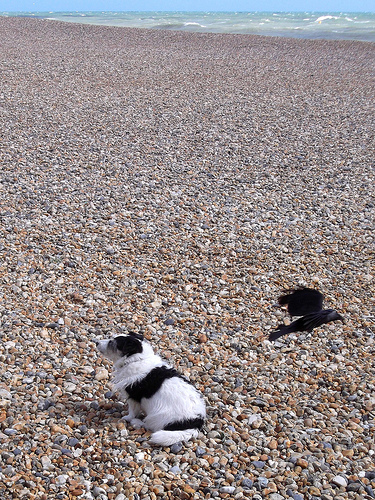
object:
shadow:
[66, 418, 74, 428]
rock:
[102, 402, 113, 410]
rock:
[39, 329, 48, 337]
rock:
[248, 414, 257, 426]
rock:
[94, 368, 107, 379]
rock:
[173, 221, 179, 227]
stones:
[136, 212, 144, 218]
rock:
[239, 477, 252, 489]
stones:
[72, 289, 82, 302]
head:
[96, 330, 144, 364]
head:
[324, 308, 346, 324]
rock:
[332, 475, 347, 487]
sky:
[0, 0, 373, 12]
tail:
[149, 428, 198, 447]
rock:
[236, 413, 249, 422]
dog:
[96, 331, 207, 447]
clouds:
[29, 0, 34, 7]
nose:
[95, 342, 98, 347]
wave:
[302, 11, 354, 31]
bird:
[268, 286, 345, 344]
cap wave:
[315, 15, 353, 22]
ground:
[220, 45, 252, 71]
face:
[96, 339, 120, 359]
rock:
[251, 461, 265, 469]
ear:
[123, 336, 143, 358]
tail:
[267, 323, 290, 341]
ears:
[127, 331, 144, 341]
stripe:
[125, 366, 178, 404]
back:
[120, 362, 201, 425]